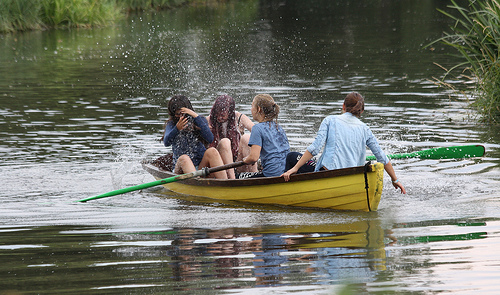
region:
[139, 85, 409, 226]
four people riding in a canoe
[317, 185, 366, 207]
yellow base of the canoe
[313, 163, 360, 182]
brown wood rail of the canoe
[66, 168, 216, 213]
a green oar in the water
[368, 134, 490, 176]
a green oar hanging over the water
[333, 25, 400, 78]
calm black water of the river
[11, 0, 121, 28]
green plants growing on the river bank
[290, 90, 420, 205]
a woman splashing water toards the children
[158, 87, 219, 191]
a girl shielding herself from the splashing water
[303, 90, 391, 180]
a woman wearing a blue shirt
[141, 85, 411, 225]
Four people are in a boat.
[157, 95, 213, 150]
A female is holding her hands up to her face.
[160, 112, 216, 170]
A female is wearing a dark top.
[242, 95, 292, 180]
A girl is wearing a blue top.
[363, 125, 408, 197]
A female has her hand out of the boat.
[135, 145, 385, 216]
The color of a boat is brown and yellow.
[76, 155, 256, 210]
The color of a paddle is green and brown.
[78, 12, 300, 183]
Water spray is in the air.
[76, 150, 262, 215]
An oar is in the water.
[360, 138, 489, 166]
An oar is out of the water.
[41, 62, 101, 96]
this is the water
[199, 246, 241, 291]
the water is blue in color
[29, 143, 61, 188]
the water has ripples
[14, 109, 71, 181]
the ripples are big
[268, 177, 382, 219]
this is a boat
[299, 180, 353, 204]
the boat is yellow in color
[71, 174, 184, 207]
this is a pedal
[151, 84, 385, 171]
these are the people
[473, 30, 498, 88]
this is the grass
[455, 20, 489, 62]
the grass is green in color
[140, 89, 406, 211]
group of girls in a boat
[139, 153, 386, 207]
yellow boat in the water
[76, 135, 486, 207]
green oars on the boat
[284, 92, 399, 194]
girl in a light blue shirt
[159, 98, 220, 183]
girl in a dark blue shirt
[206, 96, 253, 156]
girl with long brown hair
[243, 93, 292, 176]
girl with a gray shirt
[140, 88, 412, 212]
group of friends playing in a boat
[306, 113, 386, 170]
light blue shirt on the girl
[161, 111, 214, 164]
dark blue shirt on the girl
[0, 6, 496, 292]
yellow boat in the water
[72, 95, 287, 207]
girl holding green oar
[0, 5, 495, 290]
girl holding hand in water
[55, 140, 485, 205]
yellow boat with green oars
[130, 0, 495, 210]
plants beside the boat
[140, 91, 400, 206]
girls sitting in boat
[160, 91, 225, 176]
girl wearing dark blue shirt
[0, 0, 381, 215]
plants in front of boat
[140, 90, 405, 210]
girl holding onto side of the boat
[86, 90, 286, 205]
girl rowing with the oar